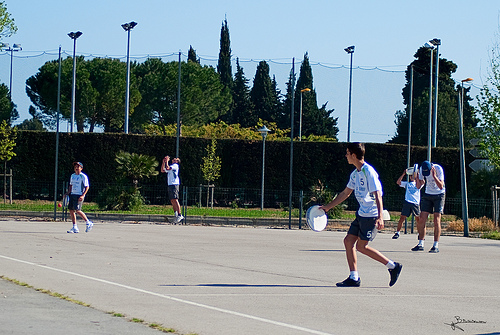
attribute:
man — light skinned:
[318, 141, 403, 288]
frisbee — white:
[305, 205, 327, 232]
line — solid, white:
[1, 255, 330, 335]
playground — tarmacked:
[0, 209, 499, 333]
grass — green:
[1, 198, 499, 240]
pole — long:
[2, 43, 22, 133]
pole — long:
[51, 48, 67, 219]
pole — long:
[120, 21, 137, 134]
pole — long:
[175, 52, 182, 159]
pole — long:
[287, 56, 296, 228]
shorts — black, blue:
[345, 211, 381, 241]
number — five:
[365, 230, 373, 240]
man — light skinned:
[411, 160, 446, 252]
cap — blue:
[421, 160, 433, 176]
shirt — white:
[343, 166, 386, 218]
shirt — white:
[415, 164, 445, 193]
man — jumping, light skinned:
[160, 154, 185, 226]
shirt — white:
[167, 165, 179, 188]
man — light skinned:
[66, 162, 94, 235]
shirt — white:
[69, 173, 90, 194]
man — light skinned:
[392, 166, 426, 241]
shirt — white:
[400, 180, 423, 202]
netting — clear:
[0, 52, 499, 149]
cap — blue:
[73, 162, 83, 168]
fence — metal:
[0, 186, 499, 234]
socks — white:
[347, 261, 396, 282]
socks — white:
[417, 240, 440, 249]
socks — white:
[68, 220, 93, 229]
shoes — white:
[63, 221, 96, 234]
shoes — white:
[171, 212, 185, 224]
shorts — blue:
[69, 195, 82, 212]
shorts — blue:
[168, 185, 180, 199]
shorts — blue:
[400, 201, 421, 218]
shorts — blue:
[422, 193, 445, 216]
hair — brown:
[347, 143, 365, 161]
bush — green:
[115, 151, 160, 207]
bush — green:
[304, 179, 344, 222]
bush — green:
[95, 185, 141, 213]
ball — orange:
[58, 201, 62, 209]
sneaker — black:
[336, 275, 361, 286]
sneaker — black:
[387, 262, 401, 285]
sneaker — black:
[390, 233, 400, 239]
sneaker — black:
[409, 246, 423, 252]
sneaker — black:
[425, 248, 439, 254]